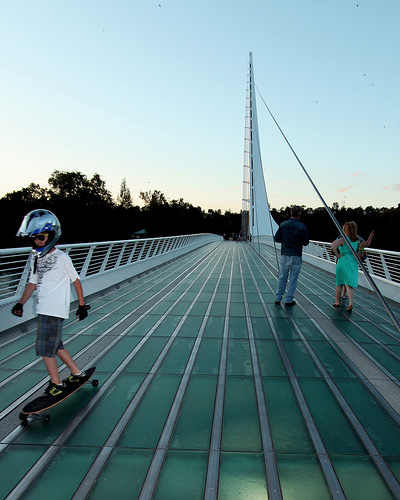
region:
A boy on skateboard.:
[4, 206, 112, 434]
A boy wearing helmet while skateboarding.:
[14, 203, 63, 264]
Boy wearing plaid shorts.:
[26, 308, 72, 359]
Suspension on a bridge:
[119, 51, 275, 371]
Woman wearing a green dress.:
[332, 236, 366, 293]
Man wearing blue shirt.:
[267, 220, 316, 257]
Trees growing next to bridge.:
[64, 167, 234, 239]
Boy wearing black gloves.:
[6, 299, 94, 321]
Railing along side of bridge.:
[100, 237, 211, 290]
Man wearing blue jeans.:
[270, 253, 310, 304]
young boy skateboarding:
[2, 214, 103, 414]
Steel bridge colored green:
[1, 232, 374, 496]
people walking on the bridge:
[264, 201, 364, 313]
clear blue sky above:
[1, 1, 393, 201]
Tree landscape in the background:
[4, 184, 396, 260]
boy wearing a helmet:
[12, 208, 64, 256]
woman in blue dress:
[324, 212, 356, 316]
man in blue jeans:
[272, 200, 301, 312]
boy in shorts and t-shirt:
[4, 208, 92, 380]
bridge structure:
[216, 40, 289, 244]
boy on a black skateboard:
[5, 190, 106, 432]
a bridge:
[3, 32, 399, 495]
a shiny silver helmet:
[8, 204, 65, 257]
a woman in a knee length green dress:
[326, 214, 366, 311]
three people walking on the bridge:
[266, 201, 376, 318]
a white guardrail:
[80, 225, 228, 300]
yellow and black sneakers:
[30, 370, 96, 403]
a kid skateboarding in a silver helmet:
[6, 201, 112, 431]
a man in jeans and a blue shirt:
[270, 201, 315, 311]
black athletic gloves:
[3, 294, 95, 324]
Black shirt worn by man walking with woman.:
[282, 220, 307, 257]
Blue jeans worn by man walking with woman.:
[279, 255, 300, 301]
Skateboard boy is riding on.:
[19, 364, 103, 424]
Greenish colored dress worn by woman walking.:
[340, 240, 357, 288]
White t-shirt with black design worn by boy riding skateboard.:
[29, 260, 70, 318]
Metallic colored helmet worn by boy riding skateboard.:
[18, 213, 60, 252]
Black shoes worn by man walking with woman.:
[272, 297, 297, 308]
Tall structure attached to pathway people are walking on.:
[246, 52, 274, 251]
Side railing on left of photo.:
[81, 231, 218, 273]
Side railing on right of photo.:
[318, 239, 399, 265]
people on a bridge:
[0, 45, 397, 495]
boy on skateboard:
[8, 205, 108, 433]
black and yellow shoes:
[32, 360, 88, 396]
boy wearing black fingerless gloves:
[4, 292, 96, 320]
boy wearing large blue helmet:
[12, 205, 64, 257]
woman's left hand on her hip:
[322, 216, 354, 264]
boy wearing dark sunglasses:
[28, 229, 48, 241]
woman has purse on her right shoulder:
[352, 233, 365, 261]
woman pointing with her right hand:
[356, 220, 376, 248]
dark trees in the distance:
[1, 168, 398, 250]